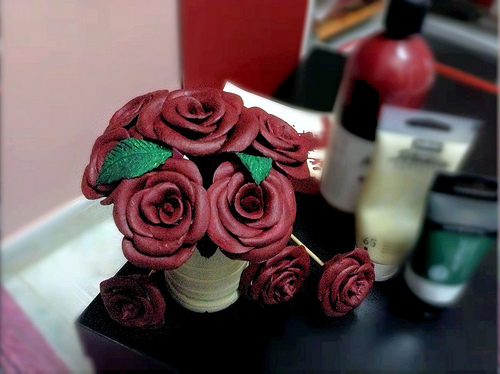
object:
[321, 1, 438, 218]
red paint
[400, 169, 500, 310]
paint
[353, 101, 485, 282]
lotion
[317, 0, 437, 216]
bottle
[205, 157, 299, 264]
clay rose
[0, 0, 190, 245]
wall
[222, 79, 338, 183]
paper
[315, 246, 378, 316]
rose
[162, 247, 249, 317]
vase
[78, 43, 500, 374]
black table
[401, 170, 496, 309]
tube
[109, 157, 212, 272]
red roses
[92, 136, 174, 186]
leaf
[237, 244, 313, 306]
bouquet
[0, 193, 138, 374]
rug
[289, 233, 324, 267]
stem